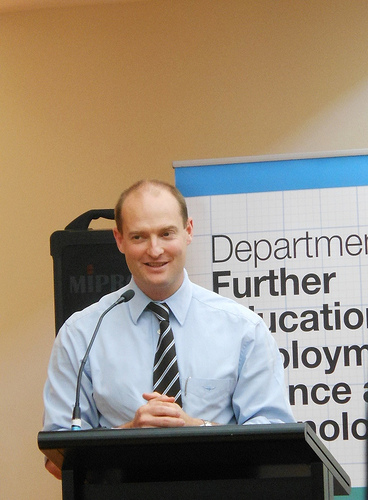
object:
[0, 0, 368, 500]
wall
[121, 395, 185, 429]
hands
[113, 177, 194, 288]
head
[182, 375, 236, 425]
pocket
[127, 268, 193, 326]
collar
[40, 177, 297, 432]
man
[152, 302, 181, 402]
striped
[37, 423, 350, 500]
podium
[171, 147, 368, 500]
sign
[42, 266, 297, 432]
blue shirt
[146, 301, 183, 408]
tie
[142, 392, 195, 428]
hands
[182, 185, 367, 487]
screen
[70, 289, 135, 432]
microphone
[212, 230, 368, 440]
writing